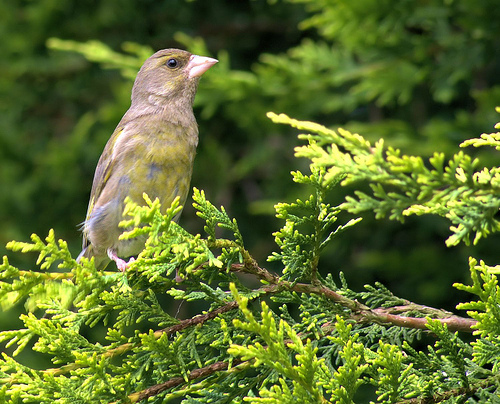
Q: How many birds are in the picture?
A: One.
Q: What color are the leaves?
A: Green.